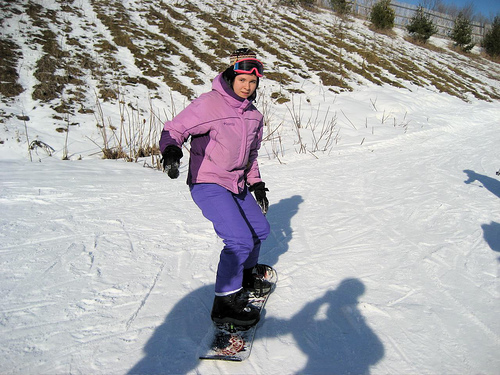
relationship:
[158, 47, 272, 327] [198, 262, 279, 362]
woman standing on snowboard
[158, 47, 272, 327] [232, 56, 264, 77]
woman wearing goggles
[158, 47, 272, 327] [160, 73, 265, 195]
woman wearing coat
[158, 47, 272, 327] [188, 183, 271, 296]
woman wearing snow pants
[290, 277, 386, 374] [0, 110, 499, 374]
shadow on snow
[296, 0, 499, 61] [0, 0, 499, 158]
trees on top of slope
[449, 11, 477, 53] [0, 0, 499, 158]
tree on top of slope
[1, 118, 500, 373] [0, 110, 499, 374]
track in snow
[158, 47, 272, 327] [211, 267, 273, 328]
woman wearing snow boots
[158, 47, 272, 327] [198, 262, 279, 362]
woman on top of snowboard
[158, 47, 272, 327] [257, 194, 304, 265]
woman has shadow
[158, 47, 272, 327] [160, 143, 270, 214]
woman wearing gloves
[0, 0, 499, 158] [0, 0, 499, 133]
slope covered with snow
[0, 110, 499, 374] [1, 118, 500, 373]
snow has tracks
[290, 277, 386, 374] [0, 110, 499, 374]
shadow on top of snow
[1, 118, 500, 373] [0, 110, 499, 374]
tracks in snow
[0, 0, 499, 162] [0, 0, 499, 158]
grass on slope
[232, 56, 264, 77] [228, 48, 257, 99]
goggles on top of head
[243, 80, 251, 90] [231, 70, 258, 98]
nose on face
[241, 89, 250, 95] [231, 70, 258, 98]
lips on face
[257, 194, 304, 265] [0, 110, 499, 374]
shadow on top of snow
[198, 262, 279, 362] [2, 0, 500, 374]
snowboard on top of ground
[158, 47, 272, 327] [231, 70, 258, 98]
woman has face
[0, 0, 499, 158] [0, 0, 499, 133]
slope covered in snow